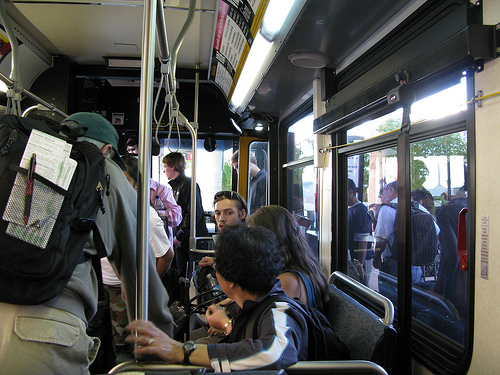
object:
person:
[117, 155, 183, 297]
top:
[205, 279, 310, 374]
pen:
[22, 152, 35, 225]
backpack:
[0, 112, 111, 306]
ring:
[148, 338, 154, 345]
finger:
[125, 335, 149, 345]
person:
[123, 220, 352, 375]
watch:
[182, 341, 195, 366]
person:
[190, 190, 249, 333]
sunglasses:
[214, 191, 244, 209]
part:
[150, 178, 184, 280]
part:
[246, 204, 330, 313]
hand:
[124, 318, 177, 361]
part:
[1, 302, 101, 375]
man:
[0, 110, 174, 374]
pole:
[134, 0, 157, 363]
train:
[2, 0, 498, 374]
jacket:
[206, 278, 309, 372]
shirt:
[374, 197, 440, 261]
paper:
[2, 129, 78, 250]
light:
[229, 0, 306, 115]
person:
[194, 205, 330, 346]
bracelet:
[224, 319, 232, 330]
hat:
[60, 111, 127, 172]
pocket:
[8, 315, 82, 375]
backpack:
[251, 294, 350, 362]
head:
[212, 190, 247, 233]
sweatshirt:
[134, 178, 183, 248]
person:
[231, 148, 268, 217]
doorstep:
[234, 130, 277, 219]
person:
[372, 180, 440, 318]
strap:
[153, 61, 172, 128]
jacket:
[167, 173, 210, 246]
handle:
[455, 207, 468, 271]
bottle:
[205, 273, 225, 296]